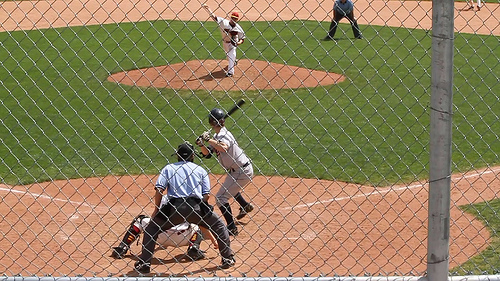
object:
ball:
[202, 4, 209, 11]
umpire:
[133, 140, 240, 275]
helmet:
[206, 107, 227, 122]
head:
[207, 107, 226, 129]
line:
[268, 149, 498, 226]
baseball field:
[28, 7, 467, 183]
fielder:
[464, 2, 485, 19]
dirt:
[1, 3, 498, 37]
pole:
[437, 0, 452, 272]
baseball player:
[194, 108, 254, 236]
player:
[174, 107, 338, 231]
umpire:
[156, 145, 236, 264]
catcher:
[109, 192, 211, 264]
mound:
[99, 45, 355, 92]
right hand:
[201, 7, 210, 12]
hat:
[229, 13, 241, 19]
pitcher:
[197, 2, 246, 80]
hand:
[348, 15, 359, 30]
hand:
[327, 13, 339, 23]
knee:
[326, 21, 341, 28]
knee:
[350, 20, 361, 32]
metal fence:
[0, 0, 498, 280]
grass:
[1, 17, 498, 187]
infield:
[2, 2, 499, 222]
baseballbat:
[197, 96, 246, 146]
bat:
[194, 92, 249, 140]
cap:
[228, 10, 239, 22]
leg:
[190, 221, 200, 261]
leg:
[121, 212, 150, 249]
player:
[199, 12, 245, 75]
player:
[321, 0, 361, 42]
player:
[135, 140, 235, 276]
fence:
[0, 2, 499, 280]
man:
[465, 0, 479, 11]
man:
[318, 0, 365, 40]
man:
[203, 2, 248, 70]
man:
[193, 103, 259, 231]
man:
[129, 138, 238, 272]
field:
[3, 0, 497, 279]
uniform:
[206, 127, 256, 233]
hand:
[195, 127, 211, 140]